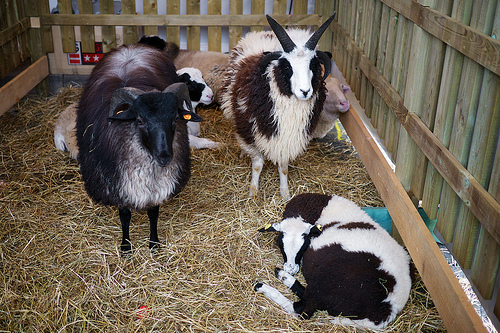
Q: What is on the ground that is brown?
A: Hay.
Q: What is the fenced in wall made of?
A: Wood.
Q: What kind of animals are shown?
A: Goats.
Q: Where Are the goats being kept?
A: A wooden pen.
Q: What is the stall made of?
A: Wood.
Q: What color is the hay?
A: Yellow.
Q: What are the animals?
A: Sheeps.